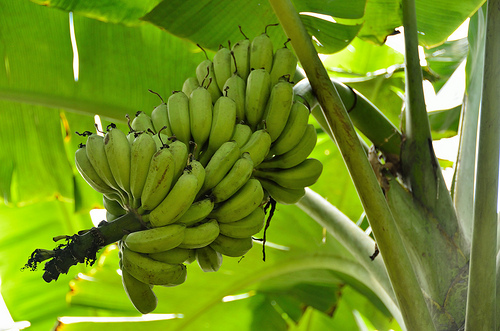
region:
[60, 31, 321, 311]
bunches of growing bananas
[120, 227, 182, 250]
an unripe green banana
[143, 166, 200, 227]
an unripe green banana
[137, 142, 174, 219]
an unripe green banana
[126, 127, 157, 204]
an unripe green banana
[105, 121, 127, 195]
an unripe green banana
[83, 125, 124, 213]
an unripe green banana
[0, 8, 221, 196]
a green banana leaf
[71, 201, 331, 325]
a green banana leaf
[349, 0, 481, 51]
a green banana leaf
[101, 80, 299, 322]
plenty bananas are visible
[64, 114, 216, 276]
plenty bananas are visible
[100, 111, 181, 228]
plenty bananas are visible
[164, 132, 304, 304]
plenty bananas are visible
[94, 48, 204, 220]
plenty bananas are visible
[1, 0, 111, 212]
large green banana tree leaves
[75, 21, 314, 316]
a bunch of ripening bananas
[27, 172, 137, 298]
thick stem on bunch of bananas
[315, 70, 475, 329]
banana tree trunk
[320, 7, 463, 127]
banana tree leaves in background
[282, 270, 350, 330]
banana tree leaves turning brown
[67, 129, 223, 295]
bottom portion of a large bunch of bananas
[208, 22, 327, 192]
top portion of a large bunch of bananas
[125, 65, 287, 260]
middle portion of a large bunch of bananas hanging in a tree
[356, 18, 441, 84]
sunlight coming through banana tree leaves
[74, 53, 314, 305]
a cluster of green bananas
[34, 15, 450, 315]
The bananas are still growing.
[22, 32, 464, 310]
The bananas are green.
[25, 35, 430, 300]
Bananas on a stem.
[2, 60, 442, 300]
The stem is thick.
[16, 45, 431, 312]
The stem is green.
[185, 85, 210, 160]
The banana is crescent-shaped.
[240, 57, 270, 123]
The banana is sickle-shaped.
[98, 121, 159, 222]
Bananas are attached to stem.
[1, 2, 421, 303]
The leaf is large.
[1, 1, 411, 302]
The leaf is green.